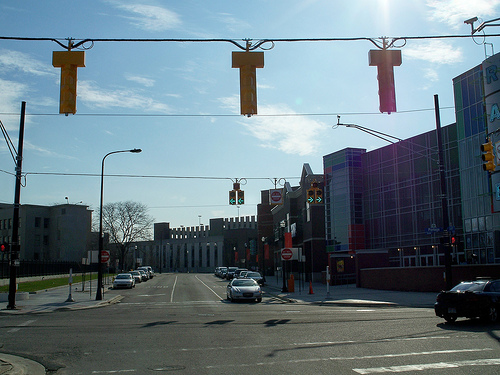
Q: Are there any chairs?
A: No, there are no chairs.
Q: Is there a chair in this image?
A: No, there are no chairs.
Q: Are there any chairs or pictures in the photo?
A: No, there are no chairs or pictures.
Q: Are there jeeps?
A: No, there are no jeeps.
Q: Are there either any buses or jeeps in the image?
A: No, there are no jeeps or buses.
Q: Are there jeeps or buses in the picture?
A: No, there are no jeeps or buses.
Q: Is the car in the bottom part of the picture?
A: Yes, the car is in the bottom of the image.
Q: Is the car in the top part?
A: No, the car is in the bottom of the image.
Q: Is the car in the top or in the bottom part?
A: The car is in the bottom of the image.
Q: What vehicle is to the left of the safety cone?
A: The vehicle is a car.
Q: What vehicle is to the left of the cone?
A: The vehicle is a car.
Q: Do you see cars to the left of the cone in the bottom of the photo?
A: Yes, there is a car to the left of the traffic cone.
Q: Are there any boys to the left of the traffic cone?
A: No, there is a car to the left of the traffic cone.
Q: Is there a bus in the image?
A: No, there are no buses.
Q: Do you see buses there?
A: No, there are no buses.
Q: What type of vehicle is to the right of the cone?
A: The vehicle is a car.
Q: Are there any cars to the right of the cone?
A: Yes, there is a car to the right of the cone.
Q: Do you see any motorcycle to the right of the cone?
A: No, there is a car to the right of the cone.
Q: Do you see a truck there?
A: No, there are no trucks.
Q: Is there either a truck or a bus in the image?
A: No, there are no trucks or buses.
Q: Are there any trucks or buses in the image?
A: No, there are no trucks or buses.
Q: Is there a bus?
A: No, there are no buses.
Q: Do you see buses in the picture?
A: No, there are no buses.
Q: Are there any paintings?
A: No, there are no paintings.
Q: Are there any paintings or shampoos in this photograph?
A: No, there are no paintings or shampoos.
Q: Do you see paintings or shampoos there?
A: No, there are no paintings or shampoos.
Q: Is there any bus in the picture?
A: No, there are no buses.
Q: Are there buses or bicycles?
A: No, there are no buses or bicycles.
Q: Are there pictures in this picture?
A: No, there are no pictures.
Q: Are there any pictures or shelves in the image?
A: No, there are no pictures or shelves.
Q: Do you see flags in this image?
A: No, there are no flags.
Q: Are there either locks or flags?
A: No, there are no flags or locks.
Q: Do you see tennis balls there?
A: No, there are no tennis balls.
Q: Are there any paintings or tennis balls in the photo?
A: No, there are no tennis balls or paintings.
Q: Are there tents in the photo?
A: No, there are no tents.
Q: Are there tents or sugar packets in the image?
A: No, there are no tents or sugar packets.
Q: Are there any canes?
A: No, there are no canes.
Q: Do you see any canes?
A: No, there are no canes.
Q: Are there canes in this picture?
A: No, there are no canes.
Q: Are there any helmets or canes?
A: No, there are no canes or helmets.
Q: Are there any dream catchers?
A: No, there are no dream catchers.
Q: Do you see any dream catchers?
A: No, there are no dream catchers.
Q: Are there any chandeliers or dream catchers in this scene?
A: No, there are no dream catchers or chandeliers.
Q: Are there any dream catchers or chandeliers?
A: No, there are no dream catchers or chandeliers.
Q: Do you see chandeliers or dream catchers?
A: No, there are no dream catchers or chandeliers.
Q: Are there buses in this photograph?
A: No, there are no buses.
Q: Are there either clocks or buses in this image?
A: No, there are no buses or clocks.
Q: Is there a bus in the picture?
A: No, there are no buses.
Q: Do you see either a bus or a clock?
A: No, there are no buses or clocks.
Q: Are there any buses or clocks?
A: No, there are no buses or clocks.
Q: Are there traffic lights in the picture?
A: Yes, there is a traffic light.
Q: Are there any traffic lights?
A: Yes, there is a traffic light.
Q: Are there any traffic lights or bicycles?
A: Yes, there is a traffic light.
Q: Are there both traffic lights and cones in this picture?
A: Yes, there are both a traffic light and a cone.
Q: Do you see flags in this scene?
A: No, there are no flags.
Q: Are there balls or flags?
A: No, there are no flags or balls.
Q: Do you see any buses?
A: No, there are no buses.